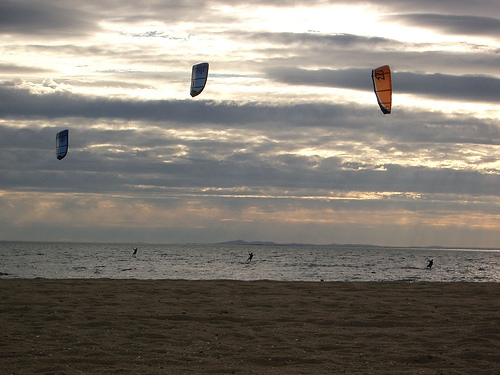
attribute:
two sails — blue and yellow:
[141, 31, 418, 200]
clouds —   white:
[1, 1, 497, 256]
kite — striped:
[186, 60, 213, 97]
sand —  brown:
[228, 281, 498, 310]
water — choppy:
[13, 244, 487, 277]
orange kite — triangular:
[371, 62, 393, 115]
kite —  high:
[178, 54, 225, 104]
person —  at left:
[134, 242, 141, 259]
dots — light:
[85, 340, 250, 363]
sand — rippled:
[6, 278, 498, 373]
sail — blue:
[187, 59, 214, 99]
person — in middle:
[230, 244, 257, 266]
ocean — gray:
[1, 240, 498, 372]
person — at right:
[417, 255, 438, 268]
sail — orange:
[371, 63, 392, 118]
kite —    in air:
[317, 12, 457, 163]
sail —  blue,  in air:
[54, 128, 75, 165]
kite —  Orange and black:
[362, 56, 405, 125]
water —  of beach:
[1, 239, 484, 282]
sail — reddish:
[370, 63, 392, 114]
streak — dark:
[2, 220, 484, 249]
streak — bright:
[0, 199, 484, 226]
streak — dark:
[42, 190, 484, 210]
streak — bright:
[130, 190, 380, 200]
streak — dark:
[1, 148, 483, 189]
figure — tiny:
[130, 244, 138, 255]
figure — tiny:
[245, 249, 255, 261]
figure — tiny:
[424, 256, 434, 269]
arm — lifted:
[130, 244, 134, 250]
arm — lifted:
[247, 250, 251, 255]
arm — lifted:
[250, 250, 252, 254]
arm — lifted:
[426, 260, 429, 263]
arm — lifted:
[428, 258, 430, 260]